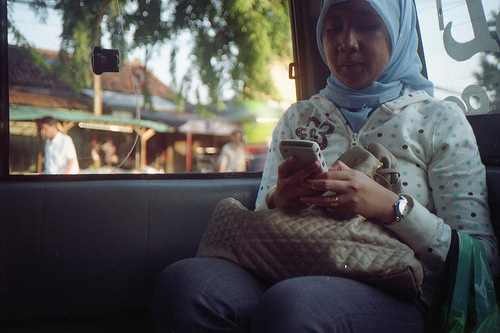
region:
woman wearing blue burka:
[134, 0, 499, 328]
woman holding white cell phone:
[146, 5, 495, 331]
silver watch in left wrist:
[361, 156, 436, 272]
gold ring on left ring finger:
[280, 135, 390, 226]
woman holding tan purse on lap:
[181, 0, 496, 329]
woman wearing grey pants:
[174, 0, 497, 327]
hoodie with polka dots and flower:
[260, 71, 495, 265]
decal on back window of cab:
[402, 0, 497, 120]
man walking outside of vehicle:
[11, 107, 103, 175]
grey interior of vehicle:
[9, 180, 260, 330]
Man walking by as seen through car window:
[4, 5, 298, 177]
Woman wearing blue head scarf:
[308, 0, 434, 110]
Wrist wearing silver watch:
[394, 190, 411, 229]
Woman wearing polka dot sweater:
[254, 95, 491, 257]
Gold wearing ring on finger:
[316, 193, 347, 206]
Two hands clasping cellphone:
[268, 135, 372, 221]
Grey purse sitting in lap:
[197, 193, 429, 298]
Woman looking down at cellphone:
[258, 3, 406, 184]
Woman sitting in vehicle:
[5, 0, 497, 332]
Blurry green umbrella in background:
[212, 92, 280, 126]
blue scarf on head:
[316, 2, 430, 128]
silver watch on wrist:
[393, 193, 410, 219]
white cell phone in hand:
[280, 139, 330, 179]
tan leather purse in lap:
[208, 197, 417, 299]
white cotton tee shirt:
[44, 134, 79, 174]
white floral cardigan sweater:
[255, 94, 493, 271]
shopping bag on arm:
[431, 228, 497, 330]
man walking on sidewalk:
[37, 114, 80, 171]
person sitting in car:
[153, 3, 493, 331]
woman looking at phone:
[155, 4, 494, 331]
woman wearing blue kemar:
[387, 8, 400, 28]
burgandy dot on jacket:
[415, 125, 425, 135]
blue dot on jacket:
[386, 117, 401, 127]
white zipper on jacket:
[346, 125, 356, 145]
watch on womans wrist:
[388, 188, 415, 221]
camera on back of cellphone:
[276, 142, 292, 157]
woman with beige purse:
[283, 214, 320, 262]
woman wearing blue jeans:
[294, 293, 313, 322]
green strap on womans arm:
[463, 259, 482, 310]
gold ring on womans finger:
[322, 192, 344, 211]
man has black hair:
[44, 114, 54, 126]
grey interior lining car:
[63, 207, 88, 237]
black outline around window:
[116, 173, 134, 180]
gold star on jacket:
[293, 112, 336, 143]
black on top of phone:
[278, 139, 315, 148]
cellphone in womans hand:
[265, 124, 333, 219]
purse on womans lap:
[282, 227, 316, 268]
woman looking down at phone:
[308, 7, 397, 94]